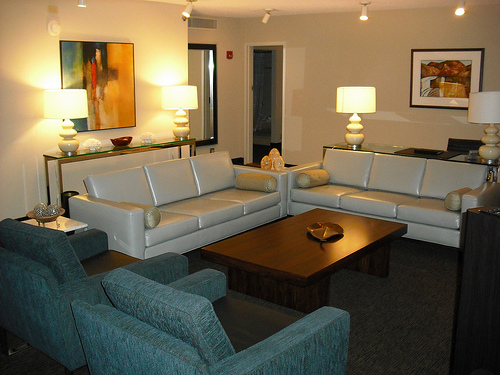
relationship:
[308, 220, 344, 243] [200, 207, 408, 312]
tray on table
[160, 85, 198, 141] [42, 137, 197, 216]
lamp on stand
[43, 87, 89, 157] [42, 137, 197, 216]
lamp on stand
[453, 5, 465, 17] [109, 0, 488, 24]
light on ceiling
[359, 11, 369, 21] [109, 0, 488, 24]
light on ceiling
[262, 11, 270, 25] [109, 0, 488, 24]
light on ceiling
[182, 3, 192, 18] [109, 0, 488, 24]
light on ceiling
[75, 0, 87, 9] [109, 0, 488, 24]
light on ceiling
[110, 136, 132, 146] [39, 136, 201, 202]
bowl on table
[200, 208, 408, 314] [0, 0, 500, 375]
table in middle of light room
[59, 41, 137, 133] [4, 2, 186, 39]
picture on wall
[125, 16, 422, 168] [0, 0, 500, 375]
white walls in light room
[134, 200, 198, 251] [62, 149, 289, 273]
cushion in couch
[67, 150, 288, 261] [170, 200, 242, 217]
couch in cushion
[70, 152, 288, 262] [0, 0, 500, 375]
couch in light room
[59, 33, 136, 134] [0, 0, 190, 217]
picture on wall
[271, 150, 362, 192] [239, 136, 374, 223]
pillow on table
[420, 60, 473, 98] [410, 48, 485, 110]
art piece in black frame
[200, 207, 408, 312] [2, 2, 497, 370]
table in livingroom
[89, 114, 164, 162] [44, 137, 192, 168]
bowl on table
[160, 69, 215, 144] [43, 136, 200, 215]
lamp sitting on table